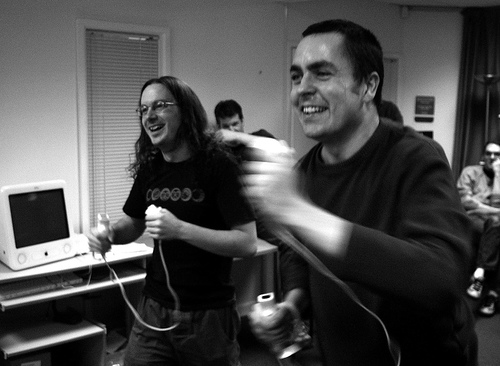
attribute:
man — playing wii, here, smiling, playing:
[225, 11, 478, 361]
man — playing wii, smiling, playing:
[94, 72, 269, 365]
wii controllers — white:
[225, 116, 297, 360]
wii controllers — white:
[93, 207, 164, 251]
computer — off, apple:
[4, 182, 73, 268]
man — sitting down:
[463, 143, 498, 315]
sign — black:
[412, 95, 435, 119]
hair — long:
[121, 79, 225, 169]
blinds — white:
[88, 28, 165, 223]